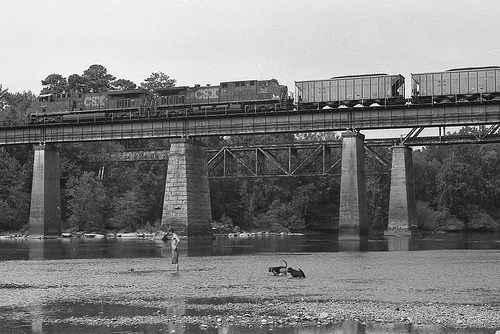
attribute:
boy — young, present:
[167, 225, 184, 271]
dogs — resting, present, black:
[264, 259, 311, 285]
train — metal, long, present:
[28, 66, 496, 102]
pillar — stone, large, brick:
[159, 140, 221, 244]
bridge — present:
[9, 104, 495, 248]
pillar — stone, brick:
[23, 141, 69, 240]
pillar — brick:
[334, 133, 430, 249]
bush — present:
[69, 172, 106, 229]